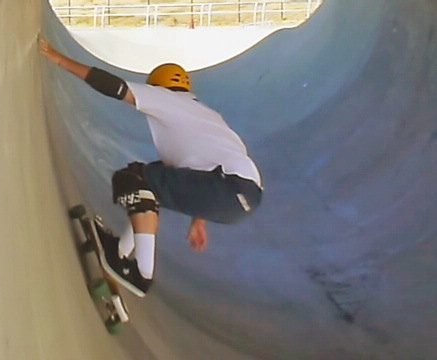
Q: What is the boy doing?
A: Skateboarding.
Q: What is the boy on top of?
A: Skateboard.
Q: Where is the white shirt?
A: On the boy.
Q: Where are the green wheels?
A: On the skateboard.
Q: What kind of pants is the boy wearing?
A: Shorts.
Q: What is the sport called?
A: Skateboarding.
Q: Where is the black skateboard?
A: Under the boy's feet.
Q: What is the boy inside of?
A: A grey concrete pipe.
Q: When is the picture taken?
A: Daytime.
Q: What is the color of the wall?
A: White.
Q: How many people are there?
A: 1.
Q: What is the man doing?
A: Skating.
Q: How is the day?
A: Sunny.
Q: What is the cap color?
A: Orange.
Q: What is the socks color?
A: White.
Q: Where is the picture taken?
A: At the skatepark.